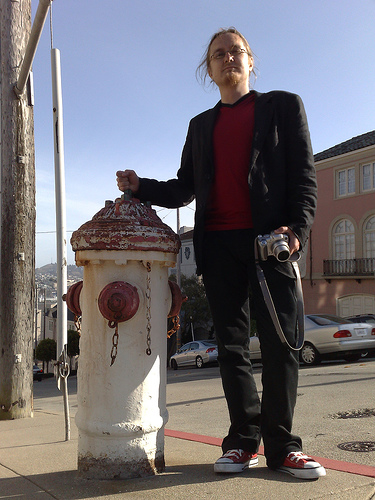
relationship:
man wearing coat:
[196, 34, 252, 116] [161, 99, 329, 239]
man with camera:
[196, 34, 252, 116] [246, 235, 301, 271]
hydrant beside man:
[63, 199, 201, 474] [196, 34, 252, 116]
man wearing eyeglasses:
[196, 34, 252, 116] [205, 46, 251, 68]